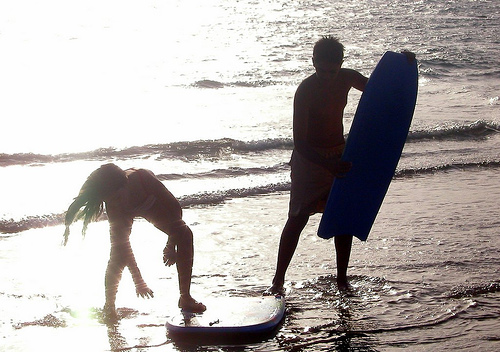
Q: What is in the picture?
A: Surfboards.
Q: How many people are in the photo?
A: Two.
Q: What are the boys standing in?
A: Water.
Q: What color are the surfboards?
A: Blue.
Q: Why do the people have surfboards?
A: To surf.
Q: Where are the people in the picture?
A: The beach.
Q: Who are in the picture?
A: People.